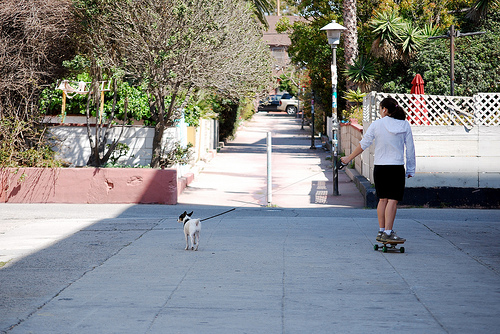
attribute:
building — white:
[23, 105, 221, 165]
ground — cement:
[1, 201, 496, 329]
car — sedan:
[276, 90, 302, 113]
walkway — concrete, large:
[186, 111, 363, 208]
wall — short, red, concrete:
[354, 126, 496, 204]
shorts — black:
[373, 163, 405, 199]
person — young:
[337, 88, 416, 244]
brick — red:
[1, 161, 198, 202]